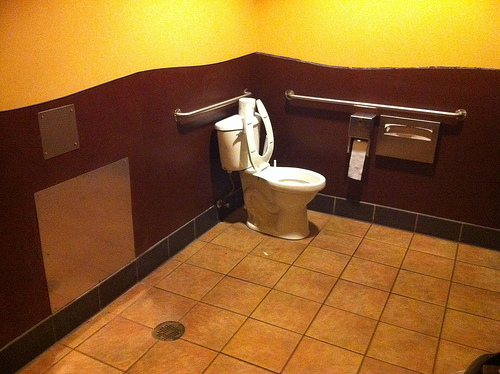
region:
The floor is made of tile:
[195, 248, 439, 336]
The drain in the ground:
[147, 311, 193, 348]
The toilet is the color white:
[213, 95, 328, 243]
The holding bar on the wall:
[283, 85, 473, 124]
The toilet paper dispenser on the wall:
[343, 109, 375, 181]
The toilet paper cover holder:
[371, 112, 443, 165]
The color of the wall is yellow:
[20, 5, 454, 49]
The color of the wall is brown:
[113, 98, 200, 238]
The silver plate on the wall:
[45, 185, 142, 276]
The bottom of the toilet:
[237, 187, 321, 240]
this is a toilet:
[164, 65, 347, 244]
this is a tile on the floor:
[323, 263, 398, 345]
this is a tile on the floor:
[196, 263, 279, 325]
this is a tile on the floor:
[354, 225, 411, 289]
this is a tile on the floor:
[374, 290, 445, 348]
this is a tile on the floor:
[76, 305, 163, 363]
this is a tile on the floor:
[168, 303, 245, 358]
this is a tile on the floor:
[287, 335, 361, 370]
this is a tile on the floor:
[445, 303, 490, 350]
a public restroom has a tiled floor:
[11, 10, 498, 370]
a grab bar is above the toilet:
[172, 83, 255, 122]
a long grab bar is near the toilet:
[274, 82, 471, 131]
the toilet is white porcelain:
[215, 100, 329, 245]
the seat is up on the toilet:
[239, 100, 274, 170]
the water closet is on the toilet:
[213, 109, 262, 173]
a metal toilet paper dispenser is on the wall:
[341, 105, 381, 162]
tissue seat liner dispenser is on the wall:
[374, 110, 437, 169]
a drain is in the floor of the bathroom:
[142, 314, 191, 346]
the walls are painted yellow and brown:
[11, 3, 499, 293]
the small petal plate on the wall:
[36, 102, 78, 159]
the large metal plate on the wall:
[32, 155, 136, 315]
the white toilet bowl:
[213, 98, 325, 238]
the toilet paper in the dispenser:
[345, 138, 366, 179]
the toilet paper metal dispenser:
[345, 108, 375, 154]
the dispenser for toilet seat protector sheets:
[373, 112, 440, 164]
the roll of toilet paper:
[237, 96, 256, 115]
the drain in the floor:
[152, 319, 184, 341]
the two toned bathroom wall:
[0, 0, 496, 350]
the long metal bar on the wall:
[283, 86, 466, 122]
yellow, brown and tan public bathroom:
[3, 3, 496, 370]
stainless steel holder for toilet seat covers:
[368, 110, 440, 168]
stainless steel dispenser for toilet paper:
[343, 106, 374, 184]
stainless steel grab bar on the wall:
[170, 90, 255, 120]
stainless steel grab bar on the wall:
[280, 89, 467, 124]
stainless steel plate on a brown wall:
[30, 153, 138, 309]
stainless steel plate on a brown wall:
[33, 102, 82, 163]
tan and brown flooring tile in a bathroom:
[19, 209, 496, 370]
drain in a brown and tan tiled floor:
[154, 317, 186, 344]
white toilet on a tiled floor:
[213, 94, 330, 241]